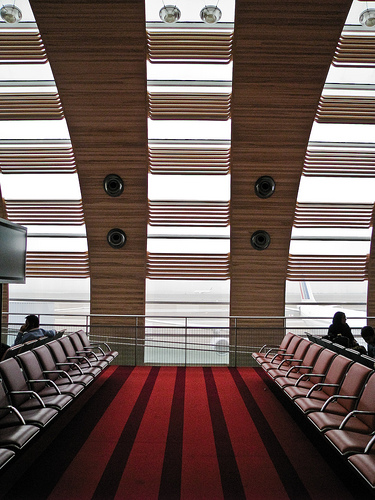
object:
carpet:
[0, 0, 375, 499]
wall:
[0, 0, 374, 318]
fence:
[0, 315, 375, 368]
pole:
[0, 311, 375, 325]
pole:
[283, 317, 286, 330]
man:
[0, 313, 54, 354]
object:
[255, 176, 275, 199]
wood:
[231, 0, 344, 354]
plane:
[283, 280, 367, 334]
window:
[145, 280, 230, 364]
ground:
[288, 467, 337, 497]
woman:
[327, 311, 365, 358]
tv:
[0, 218, 27, 285]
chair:
[252, 331, 375, 493]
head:
[24, 314, 39, 330]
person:
[360, 326, 374, 357]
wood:
[26, 0, 149, 359]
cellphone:
[22, 323, 29, 329]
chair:
[0, 329, 119, 473]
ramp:
[135, 315, 236, 363]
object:
[107, 228, 126, 248]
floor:
[113, 367, 256, 499]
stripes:
[212, 440, 245, 497]